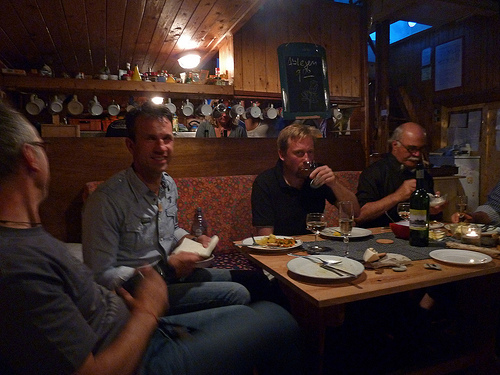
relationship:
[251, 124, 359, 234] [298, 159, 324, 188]
man drinking from glass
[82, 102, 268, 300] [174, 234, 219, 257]
man holding napkin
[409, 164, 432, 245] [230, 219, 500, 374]
wine bottle sitting on table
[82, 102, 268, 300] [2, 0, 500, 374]
man at a restaurant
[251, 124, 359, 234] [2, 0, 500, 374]
man at a restaurant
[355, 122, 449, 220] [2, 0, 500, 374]
man at a restaurant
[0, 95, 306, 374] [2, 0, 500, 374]
man at a restaurant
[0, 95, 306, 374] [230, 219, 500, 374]
man sitting at table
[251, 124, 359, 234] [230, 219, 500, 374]
man sitting at table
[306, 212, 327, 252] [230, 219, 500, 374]
wine glass sitting on table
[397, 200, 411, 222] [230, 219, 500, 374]
wine glass sitting on table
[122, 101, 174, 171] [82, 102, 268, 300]
head of a man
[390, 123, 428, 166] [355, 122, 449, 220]
head of a man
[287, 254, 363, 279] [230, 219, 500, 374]
plate sitting on top of table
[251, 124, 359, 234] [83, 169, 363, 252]
man sitting on bench back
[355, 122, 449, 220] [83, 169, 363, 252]
man sitting on bench back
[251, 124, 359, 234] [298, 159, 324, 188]
man sipping from glass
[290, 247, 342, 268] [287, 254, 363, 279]
fork sitting on plate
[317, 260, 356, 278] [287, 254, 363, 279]
knife sitting on plate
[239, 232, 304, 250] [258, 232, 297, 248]
plate of food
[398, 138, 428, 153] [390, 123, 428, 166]
glasses sitting on man's head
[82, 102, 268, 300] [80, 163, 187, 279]
man wearing shirt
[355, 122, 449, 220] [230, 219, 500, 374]
man sitting at table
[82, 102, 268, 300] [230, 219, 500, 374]
man sitting at table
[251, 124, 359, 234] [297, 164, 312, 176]
man drinking drink